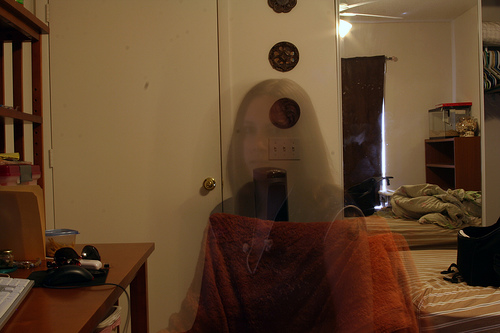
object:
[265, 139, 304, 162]
switches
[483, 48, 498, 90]
hangers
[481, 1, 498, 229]
closet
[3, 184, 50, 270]
file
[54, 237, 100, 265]
sunglasses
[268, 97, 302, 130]
circle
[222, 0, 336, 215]
wall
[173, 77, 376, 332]
reflection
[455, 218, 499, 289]
bag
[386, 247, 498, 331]
bed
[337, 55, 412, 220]
curtains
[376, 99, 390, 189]
window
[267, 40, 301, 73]
circle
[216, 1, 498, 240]
mirror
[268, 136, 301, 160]
light switch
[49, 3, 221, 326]
door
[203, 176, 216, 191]
knob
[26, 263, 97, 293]
mouse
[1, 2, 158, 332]
desk